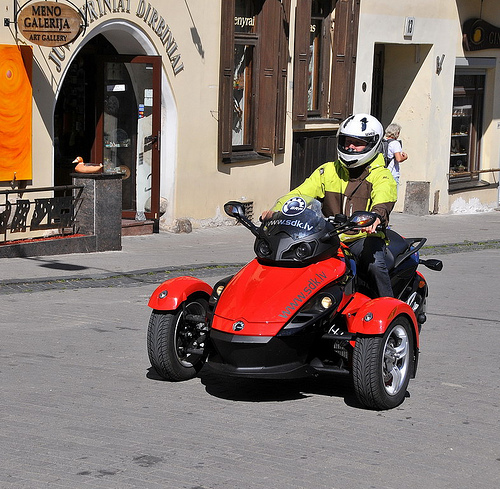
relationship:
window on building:
[308, 2, 342, 125] [2, 0, 498, 212]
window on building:
[234, 41, 255, 147] [2, 0, 498, 212]